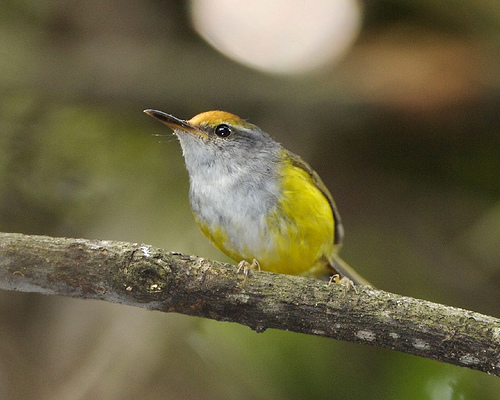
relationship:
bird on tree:
[141, 107, 376, 297] [6, 224, 479, 369]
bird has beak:
[144, 103, 376, 289] [142, 107, 208, 139]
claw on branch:
[231, 259, 262, 282] [0, 230, 500, 378]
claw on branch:
[322, 269, 364, 298] [0, 230, 500, 378]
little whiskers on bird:
[150, 129, 177, 149] [144, 103, 376, 289]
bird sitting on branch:
[141, 107, 376, 297] [0, 229, 499, 378]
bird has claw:
[144, 103, 376, 289] [235, 258, 261, 282]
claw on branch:
[235, 258, 261, 282] [0, 229, 499, 378]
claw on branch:
[327, 273, 362, 298] [0, 229, 499, 378]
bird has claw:
[144, 103, 376, 289] [327, 273, 362, 298]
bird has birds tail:
[144, 103, 376, 289] [326, 253, 376, 288]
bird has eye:
[144, 103, 376, 289] [212, 124, 235, 139]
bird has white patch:
[144, 103, 376, 289] [175, 130, 282, 252]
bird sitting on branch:
[144, 103, 376, 289] [0, 230, 500, 378]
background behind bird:
[1, 0, 498, 398] [144, 103, 376, 289]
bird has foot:
[144, 103, 376, 289] [234, 255, 260, 278]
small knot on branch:
[120, 261, 168, 296] [0, 229, 499, 378]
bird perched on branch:
[144, 103, 376, 289] [0, 229, 499, 378]